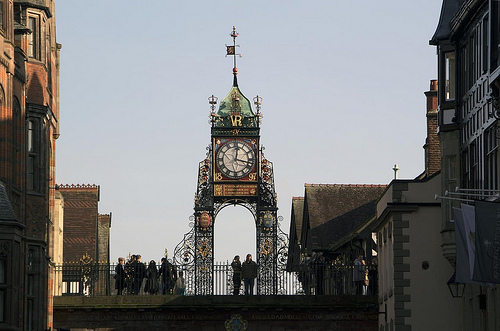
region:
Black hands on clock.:
[221, 138, 263, 175]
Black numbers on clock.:
[216, 132, 254, 207]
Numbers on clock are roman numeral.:
[213, 140, 284, 205]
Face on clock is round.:
[218, 137, 271, 221]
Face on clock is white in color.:
[215, 132, 271, 193]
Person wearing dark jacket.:
[241, 260, 267, 288]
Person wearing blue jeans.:
[239, 274, 254, 290]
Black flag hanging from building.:
[466, 199, 498, 284]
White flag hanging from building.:
[452, 198, 478, 280]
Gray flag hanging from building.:
[443, 187, 467, 283]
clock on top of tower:
[216, 137, 261, 178]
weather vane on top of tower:
[222, 25, 250, 88]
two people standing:
[218, 255, 264, 287]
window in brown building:
[23, 13, 55, 85]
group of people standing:
[112, 252, 189, 297]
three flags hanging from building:
[448, 190, 495, 291]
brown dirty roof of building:
[301, 176, 383, 233]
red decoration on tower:
[195, 210, 212, 233]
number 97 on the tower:
[245, 169, 259, 184]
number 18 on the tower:
[211, 170, 224, 182]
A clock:
[187, 119, 271, 178]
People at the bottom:
[78, 221, 415, 297]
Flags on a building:
[411, 161, 498, 303]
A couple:
[213, 242, 279, 298]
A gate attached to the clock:
[55, 237, 392, 309]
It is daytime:
[81, 12, 196, 178]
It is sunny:
[74, 18, 184, 181]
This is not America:
[4, 6, 199, 327]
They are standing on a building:
[52, 267, 353, 327]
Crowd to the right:
[283, 232, 379, 303]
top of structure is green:
[175, 77, 274, 122]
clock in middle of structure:
[212, 135, 259, 185]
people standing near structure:
[120, 222, 272, 301]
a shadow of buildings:
[3, 61, 67, 306]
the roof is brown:
[295, 170, 420, 219]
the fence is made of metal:
[60, 250, 347, 304]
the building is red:
[0, 4, 53, 326]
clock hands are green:
[215, 131, 255, 178]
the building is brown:
[353, 167, 497, 329]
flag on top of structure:
[214, 35, 245, 63]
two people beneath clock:
[209, 131, 254, 298]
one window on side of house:
[24, 11, 54, 63]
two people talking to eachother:
[222, 247, 259, 297]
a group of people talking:
[108, 249, 185, 304]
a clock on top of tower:
[205, 138, 259, 192]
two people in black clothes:
[208, 242, 301, 304]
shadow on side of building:
[8, 61, 83, 330]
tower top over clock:
[192, 19, 285, 158]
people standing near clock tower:
[108, 243, 178, 311]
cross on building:
[375, 155, 405, 205]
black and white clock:
[215, 144, 257, 180]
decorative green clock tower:
[181, 79, 278, 302]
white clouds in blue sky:
[298, 99, 331, 138]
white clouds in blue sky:
[254, 1, 285, 34]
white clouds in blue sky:
[133, 168, 158, 205]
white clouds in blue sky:
[112, 110, 150, 142]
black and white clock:
[212, 132, 262, 176]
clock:
[215, 138, 263, 176]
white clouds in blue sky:
[301, 25, 346, 62]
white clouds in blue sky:
[311, 144, 346, 174]